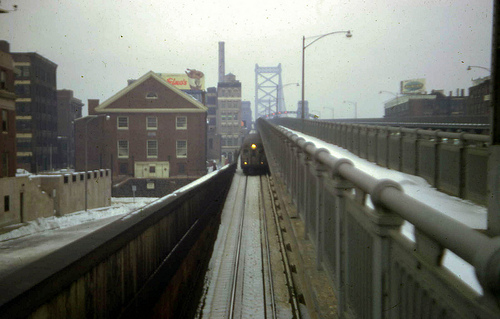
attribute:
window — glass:
[203, 102, 219, 115]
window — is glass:
[118, 114, 127, 131]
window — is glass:
[141, 113, 161, 133]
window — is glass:
[173, 111, 187, 133]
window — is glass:
[173, 138, 188, 159]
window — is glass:
[142, 137, 161, 159]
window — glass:
[145, 115, 155, 130]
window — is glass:
[145, 88, 158, 103]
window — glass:
[174, 136, 190, 160]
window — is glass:
[145, 113, 158, 129]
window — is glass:
[115, 138, 126, 158]